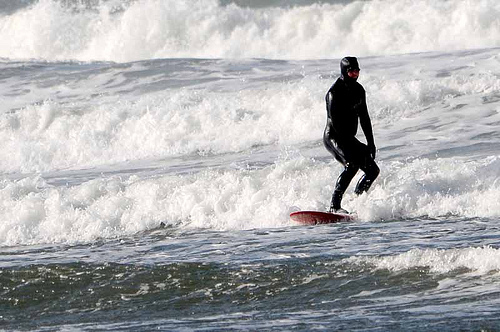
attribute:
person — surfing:
[324, 57, 381, 214]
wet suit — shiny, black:
[325, 57, 377, 213]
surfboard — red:
[290, 210, 360, 227]